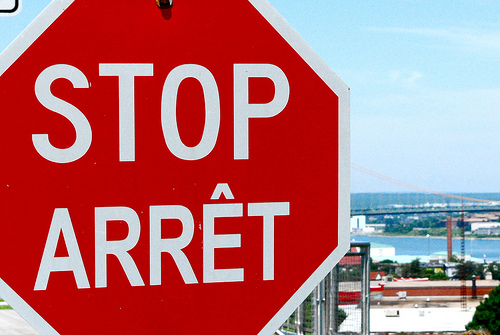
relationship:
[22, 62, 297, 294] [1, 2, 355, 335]
letters on sign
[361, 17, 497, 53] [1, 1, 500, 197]
clouds in sky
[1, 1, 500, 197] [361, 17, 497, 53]
sky with clouds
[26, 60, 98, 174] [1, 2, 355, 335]
s on sign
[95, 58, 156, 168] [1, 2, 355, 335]
t on sign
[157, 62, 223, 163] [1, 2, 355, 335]
o on sign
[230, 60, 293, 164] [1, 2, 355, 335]
p on sign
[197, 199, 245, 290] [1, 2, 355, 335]
e on sign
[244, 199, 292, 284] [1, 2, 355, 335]
t on sign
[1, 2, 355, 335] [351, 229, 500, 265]
sign on water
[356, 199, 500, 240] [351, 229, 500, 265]
buildings in front of water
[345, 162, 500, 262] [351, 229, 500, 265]
bridge over water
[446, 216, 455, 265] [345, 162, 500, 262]
columns of bridge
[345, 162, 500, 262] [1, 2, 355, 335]
bridge behind sign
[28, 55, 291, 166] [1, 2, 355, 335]
stop on sign